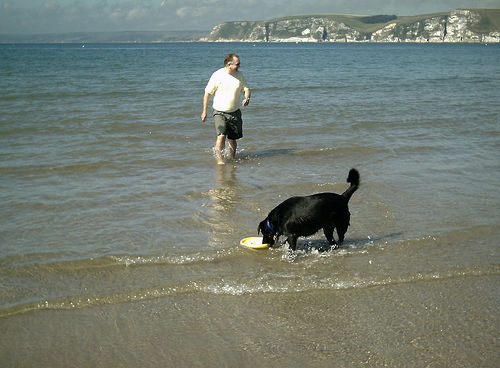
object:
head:
[256, 216, 280, 246]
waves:
[0, 205, 499, 320]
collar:
[262, 217, 274, 232]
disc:
[239, 234, 269, 251]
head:
[224, 53, 242, 75]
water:
[0, 42, 499, 367]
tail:
[339, 166, 362, 204]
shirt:
[200, 64, 252, 112]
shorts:
[212, 108, 245, 141]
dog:
[255, 166, 360, 251]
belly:
[210, 92, 244, 112]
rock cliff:
[194, 10, 499, 45]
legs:
[322, 227, 334, 247]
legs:
[336, 224, 350, 246]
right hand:
[193, 110, 208, 124]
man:
[197, 52, 252, 166]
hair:
[223, 53, 241, 68]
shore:
[0, 225, 499, 367]